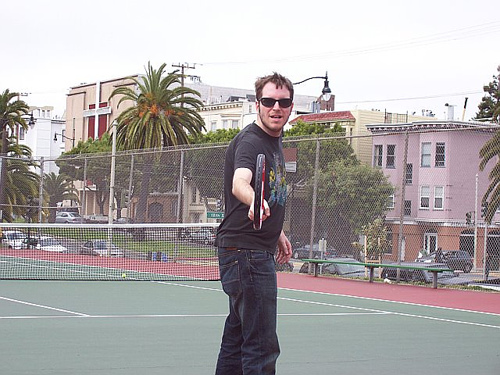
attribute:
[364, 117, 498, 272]
building — pink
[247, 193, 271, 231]
hand — right hand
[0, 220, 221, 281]
net — stretched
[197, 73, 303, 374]
player — standing, holding, throwing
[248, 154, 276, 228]
racket — tennis racket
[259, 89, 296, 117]
sunglasses — black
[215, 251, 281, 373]
jean — blue, black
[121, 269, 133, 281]
ball — yellow, tennis ball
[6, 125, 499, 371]
tennis court — green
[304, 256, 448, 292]
bench — green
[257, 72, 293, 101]
hair — brown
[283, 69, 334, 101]
lamp post — black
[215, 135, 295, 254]
shirt — black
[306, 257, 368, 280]
car — brown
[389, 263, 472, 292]
truck — black, parked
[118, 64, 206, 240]
tree — palm tree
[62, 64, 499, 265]
home — pink